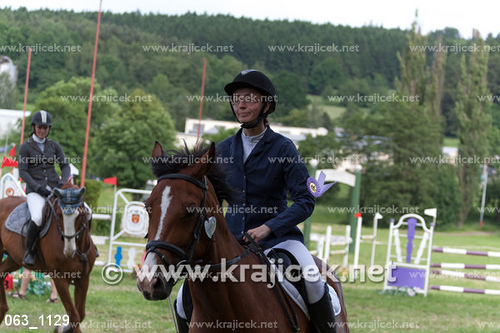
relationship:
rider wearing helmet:
[170, 70, 335, 333] [223, 67, 280, 112]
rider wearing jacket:
[196, 67, 341, 330] [206, 130, 320, 244]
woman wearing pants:
[14, 109, 100, 268] [25, 191, 46, 226]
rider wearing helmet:
[170, 70, 335, 333] [221, 69, 273, 103]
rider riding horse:
[170, 70, 335, 333] [137, 140, 348, 332]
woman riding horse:
[9, 105, 97, 262] [0, 184, 95, 331]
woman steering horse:
[14, 109, 100, 268] [0, 196, 101, 324]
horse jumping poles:
[137, 140, 348, 332] [430, 243, 498, 300]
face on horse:
[138, 170, 208, 291] [80, 133, 344, 331]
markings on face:
[143, 180, 183, 281] [138, 170, 208, 291]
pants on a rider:
[229, 210, 346, 315] [170, 70, 335, 333]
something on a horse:
[143, 168, 215, 258] [137, 140, 348, 332]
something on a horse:
[52, 186, 84, 244] [0, 184, 95, 331]